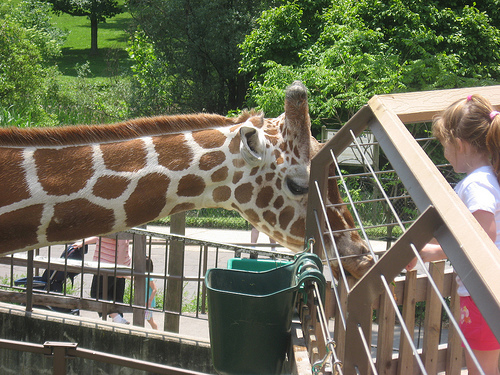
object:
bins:
[205, 253, 324, 374]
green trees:
[0, 14, 61, 125]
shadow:
[56, 46, 136, 78]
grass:
[68, 20, 89, 47]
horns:
[284, 85, 311, 141]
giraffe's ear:
[238, 127, 264, 161]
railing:
[305, 83, 500, 374]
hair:
[1, 112, 235, 146]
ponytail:
[485, 114, 499, 187]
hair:
[145, 256, 154, 273]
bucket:
[227, 258, 297, 273]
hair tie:
[489, 111, 499, 121]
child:
[405, 94, 500, 375]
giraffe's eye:
[286, 176, 309, 196]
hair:
[432, 94, 499, 183]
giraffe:
[1, 80, 378, 281]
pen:
[1, 84, 498, 374]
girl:
[71, 234, 134, 326]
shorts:
[458, 294, 499, 350]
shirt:
[91, 234, 135, 279]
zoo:
[0, 82, 499, 372]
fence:
[0, 228, 304, 347]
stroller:
[14, 240, 89, 316]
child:
[115, 256, 158, 330]